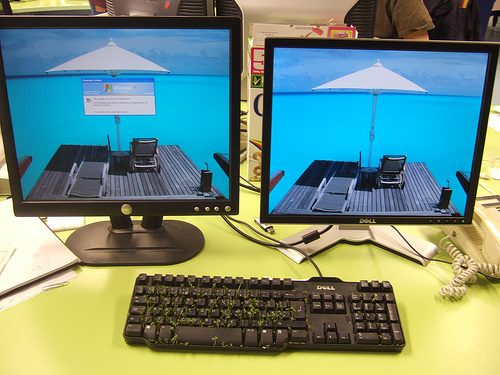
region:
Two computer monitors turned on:
[0, 13, 497, 278]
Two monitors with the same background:
[1, 10, 492, 270]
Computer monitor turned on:
[263, 33, 493, 270]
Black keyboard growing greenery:
[121, 265, 411, 355]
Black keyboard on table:
[122, 270, 411, 362]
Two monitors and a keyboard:
[1, 9, 498, 354]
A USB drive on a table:
[254, 210, 277, 235]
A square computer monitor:
[0, 10, 247, 272]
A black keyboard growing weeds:
[124, 265, 411, 366]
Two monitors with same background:
[0, 10, 485, 271]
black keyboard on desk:
[119, 263, 414, 343]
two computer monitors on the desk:
[0, 17, 488, 233]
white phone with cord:
[438, 199, 496, 304]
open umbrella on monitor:
[304, 55, 431, 155]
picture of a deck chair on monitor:
[369, 147, 421, 197]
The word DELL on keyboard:
[306, 270, 351, 301]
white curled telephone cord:
[436, 235, 498, 307]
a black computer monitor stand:
[64, 204, 214, 266]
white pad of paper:
[0, 195, 80, 315]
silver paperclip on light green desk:
[28, 276, 77, 298]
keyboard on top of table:
[113, 252, 440, 364]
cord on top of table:
[429, 222, 499, 294]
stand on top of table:
[56, 223, 241, 275]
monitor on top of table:
[0, 5, 261, 252]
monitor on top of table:
[246, 13, 498, 243]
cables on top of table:
[237, 232, 441, 279]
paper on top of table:
[0, 188, 60, 290]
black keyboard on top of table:
[89, 262, 434, 357]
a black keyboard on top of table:
[115, 271, 422, 353]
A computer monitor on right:
[262, 32, 499, 242]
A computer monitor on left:
[1, 14, 243, 226]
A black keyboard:
[111, 267, 403, 359]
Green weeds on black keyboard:
[132, 280, 312, 359]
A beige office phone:
[452, 222, 497, 297]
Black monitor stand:
[70, 218, 203, 260]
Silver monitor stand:
[282, 227, 432, 270]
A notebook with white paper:
[9, 227, 86, 313]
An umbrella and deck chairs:
[293, 66, 445, 214]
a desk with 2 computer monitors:
[7, 9, 485, 356]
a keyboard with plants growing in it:
[118, 256, 453, 367]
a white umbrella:
[316, 54, 426, 159]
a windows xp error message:
[52, 64, 179, 140]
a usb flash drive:
[250, 210, 285, 245]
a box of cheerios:
[250, 18, 290, 123]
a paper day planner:
[2, 228, 82, 306]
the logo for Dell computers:
[349, 208, 377, 233]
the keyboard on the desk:
[130, 249, 400, 362]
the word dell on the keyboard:
[308, 275, 338, 291]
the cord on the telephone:
[435, 230, 491, 311]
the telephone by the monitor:
[445, 173, 497, 283]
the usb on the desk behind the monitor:
[245, 215, 278, 240]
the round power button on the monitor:
[107, 197, 138, 222]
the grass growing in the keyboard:
[134, 273, 315, 350]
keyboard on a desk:
[121, 266, 411, 361]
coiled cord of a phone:
[434, 231, 499, 306]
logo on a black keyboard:
[312, 279, 337, 294]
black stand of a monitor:
[63, 216, 208, 270]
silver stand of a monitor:
[275, 222, 438, 270]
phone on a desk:
[430, 191, 498, 284]